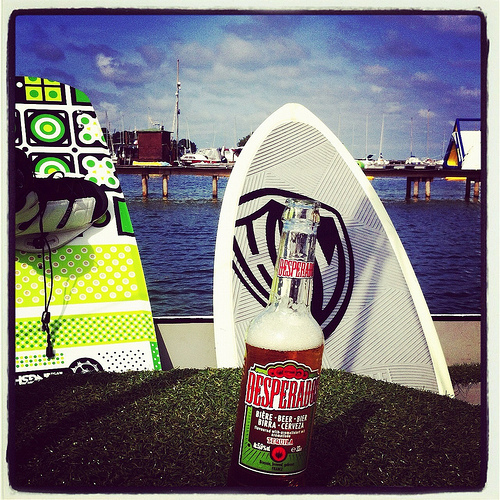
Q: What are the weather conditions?
A: It is cloudy.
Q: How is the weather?
A: It is cloudy.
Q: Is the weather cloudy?
A: Yes, it is cloudy.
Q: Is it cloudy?
A: Yes, it is cloudy.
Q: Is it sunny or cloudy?
A: It is cloudy.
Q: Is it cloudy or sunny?
A: It is cloudy.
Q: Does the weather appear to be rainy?
A: No, it is cloudy.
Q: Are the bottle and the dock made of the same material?
A: No, the bottle is made of glass and the dock is made of wood.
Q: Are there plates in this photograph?
A: No, there are no plates.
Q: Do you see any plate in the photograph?
A: No, there are no plates.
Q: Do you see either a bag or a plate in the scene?
A: No, there are no plates or bags.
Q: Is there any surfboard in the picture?
A: Yes, there is a surfboard.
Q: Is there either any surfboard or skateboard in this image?
A: Yes, there is a surfboard.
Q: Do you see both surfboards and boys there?
A: No, there is a surfboard but no boys.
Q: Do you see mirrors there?
A: No, there are no mirrors.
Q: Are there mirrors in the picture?
A: No, there are no mirrors.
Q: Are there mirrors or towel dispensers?
A: No, there are no mirrors or towel dispensers.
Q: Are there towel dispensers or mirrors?
A: No, there are no mirrors or towel dispensers.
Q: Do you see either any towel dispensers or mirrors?
A: No, there are no mirrors or towel dispensers.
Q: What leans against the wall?
A: The surf board leans against the wall.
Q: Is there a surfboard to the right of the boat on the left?
A: Yes, there is a surfboard to the right of the boat.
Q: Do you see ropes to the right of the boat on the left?
A: No, there is a surfboard to the right of the boat.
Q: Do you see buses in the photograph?
A: No, there are no buses.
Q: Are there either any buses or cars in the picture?
A: No, there are no buses or cars.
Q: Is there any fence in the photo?
A: No, there are no fences.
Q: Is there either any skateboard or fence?
A: No, there are no fences or skateboards.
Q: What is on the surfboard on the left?
A: The shoe is on the surfboard.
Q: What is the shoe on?
A: The shoe is on the surfboard.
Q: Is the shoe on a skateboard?
A: No, the shoe is on a surfboard.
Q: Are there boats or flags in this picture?
A: Yes, there is a boat.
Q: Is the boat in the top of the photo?
A: Yes, the boat is in the top of the image.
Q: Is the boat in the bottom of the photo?
A: No, the boat is in the top of the image.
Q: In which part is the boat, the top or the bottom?
A: The boat is in the top of the image.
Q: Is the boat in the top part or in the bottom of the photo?
A: The boat is in the top of the image.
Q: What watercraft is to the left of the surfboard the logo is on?
A: The watercraft is a boat.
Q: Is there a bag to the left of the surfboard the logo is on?
A: No, there is a boat to the left of the surfboard.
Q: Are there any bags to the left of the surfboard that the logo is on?
A: No, there is a boat to the left of the surfboard.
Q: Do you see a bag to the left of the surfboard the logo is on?
A: No, there is a boat to the left of the surfboard.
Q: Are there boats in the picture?
A: Yes, there is a boat.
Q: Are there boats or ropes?
A: Yes, there is a boat.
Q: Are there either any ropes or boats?
A: Yes, there is a boat.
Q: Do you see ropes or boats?
A: Yes, there is a boat.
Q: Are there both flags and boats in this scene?
A: No, there is a boat but no flags.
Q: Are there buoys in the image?
A: No, there are no buoys.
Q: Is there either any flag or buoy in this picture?
A: No, there are no buoys or flags.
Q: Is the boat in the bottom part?
A: No, the boat is in the top of the image.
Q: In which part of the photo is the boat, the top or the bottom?
A: The boat is in the top of the image.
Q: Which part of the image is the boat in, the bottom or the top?
A: The boat is in the top of the image.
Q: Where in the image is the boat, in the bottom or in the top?
A: The boat is in the top of the image.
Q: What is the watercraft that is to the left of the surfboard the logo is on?
A: The watercraft is a boat.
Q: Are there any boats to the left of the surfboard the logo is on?
A: Yes, there is a boat to the left of the surf board.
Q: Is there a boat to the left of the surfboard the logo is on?
A: Yes, there is a boat to the left of the surf board.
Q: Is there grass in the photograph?
A: Yes, there is grass.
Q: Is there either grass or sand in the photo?
A: Yes, there is grass.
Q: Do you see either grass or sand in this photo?
A: Yes, there is grass.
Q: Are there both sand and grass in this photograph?
A: No, there is grass but no sand.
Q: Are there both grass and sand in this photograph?
A: No, there is grass but no sand.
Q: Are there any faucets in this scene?
A: No, there are no faucets.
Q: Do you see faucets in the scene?
A: No, there are no faucets.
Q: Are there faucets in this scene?
A: No, there are no faucets.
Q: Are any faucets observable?
A: No, there are no faucets.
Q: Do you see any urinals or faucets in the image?
A: No, there are no faucets or urinals.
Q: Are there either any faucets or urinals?
A: No, there are no faucets or urinals.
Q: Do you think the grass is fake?
A: Yes, the grass is fake.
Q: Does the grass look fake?
A: Yes, the grass is fake.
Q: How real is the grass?
A: The grass is fake.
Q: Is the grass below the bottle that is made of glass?
A: Yes, the grass is below the bottle.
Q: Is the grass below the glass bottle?
A: Yes, the grass is below the bottle.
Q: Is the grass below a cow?
A: No, the grass is below the bottle.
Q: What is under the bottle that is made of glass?
A: The grass is under the bottle.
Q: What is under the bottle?
A: The grass is under the bottle.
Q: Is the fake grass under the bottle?
A: Yes, the grass is under the bottle.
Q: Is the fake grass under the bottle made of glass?
A: Yes, the grass is under the bottle.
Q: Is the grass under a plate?
A: No, the grass is under the bottle.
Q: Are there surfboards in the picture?
A: Yes, there is a surfboard.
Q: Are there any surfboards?
A: Yes, there is a surfboard.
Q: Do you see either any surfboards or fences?
A: Yes, there is a surfboard.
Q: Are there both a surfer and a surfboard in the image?
A: No, there is a surfboard but no surfers.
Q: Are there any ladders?
A: No, there are no ladders.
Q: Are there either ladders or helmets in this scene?
A: No, there are no ladders or helmets.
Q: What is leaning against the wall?
A: The surfboard is leaning against the wall.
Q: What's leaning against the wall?
A: The surfboard is leaning against the wall.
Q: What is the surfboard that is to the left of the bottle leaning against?
A: The surfboard is leaning against the wall.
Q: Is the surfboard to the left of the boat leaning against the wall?
A: Yes, the surfboard is leaning against the wall.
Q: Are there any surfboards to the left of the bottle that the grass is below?
A: Yes, there is a surfboard to the left of the bottle.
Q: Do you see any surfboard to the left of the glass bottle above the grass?
A: Yes, there is a surfboard to the left of the bottle.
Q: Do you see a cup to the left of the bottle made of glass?
A: No, there is a surfboard to the left of the bottle.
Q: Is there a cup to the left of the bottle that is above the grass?
A: No, there is a surfboard to the left of the bottle.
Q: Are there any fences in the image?
A: No, there are no fences.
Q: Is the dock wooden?
A: Yes, the dock is wooden.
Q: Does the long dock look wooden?
A: Yes, the pier is wooden.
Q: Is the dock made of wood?
A: Yes, the dock is made of wood.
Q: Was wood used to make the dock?
A: Yes, the dock is made of wood.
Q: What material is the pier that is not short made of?
A: The pier is made of wood.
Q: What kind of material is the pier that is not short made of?
A: The pier is made of wood.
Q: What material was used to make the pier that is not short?
A: The pier is made of wood.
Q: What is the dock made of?
A: The pier is made of wood.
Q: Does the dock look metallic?
A: No, the dock is wooden.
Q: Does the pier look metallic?
A: No, the pier is wooden.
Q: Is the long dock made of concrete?
A: No, the dock is made of wood.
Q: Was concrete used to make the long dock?
A: No, the dock is made of wood.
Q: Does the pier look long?
A: Yes, the pier is long.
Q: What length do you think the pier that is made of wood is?
A: The pier is long.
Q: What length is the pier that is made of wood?
A: The pier is long.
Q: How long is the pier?
A: The pier is long.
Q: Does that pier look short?
A: No, the pier is long.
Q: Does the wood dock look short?
A: No, the pier is long.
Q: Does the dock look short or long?
A: The dock is long.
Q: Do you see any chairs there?
A: No, there are no chairs.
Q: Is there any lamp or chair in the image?
A: No, there are no chairs or lamps.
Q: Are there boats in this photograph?
A: Yes, there is a boat.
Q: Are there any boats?
A: Yes, there is a boat.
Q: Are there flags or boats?
A: Yes, there is a boat.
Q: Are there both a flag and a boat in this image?
A: No, there is a boat but no flags.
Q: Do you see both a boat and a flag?
A: No, there is a boat but no flags.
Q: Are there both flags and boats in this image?
A: No, there is a boat but no flags.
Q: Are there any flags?
A: No, there are no flags.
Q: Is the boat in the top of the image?
A: Yes, the boat is in the top of the image.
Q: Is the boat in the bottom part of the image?
A: No, the boat is in the top of the image.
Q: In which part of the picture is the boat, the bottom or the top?
A: The boat is in the top of the image.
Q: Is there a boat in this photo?
A: Yes, there is a boat.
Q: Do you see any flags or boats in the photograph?
A: Yes, there is a boat.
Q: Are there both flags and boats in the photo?
A: No, there is a boat but no flags.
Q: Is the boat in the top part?
A: Yes, the boat is in the top of the image.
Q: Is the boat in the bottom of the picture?
A: No, the boat is in the top of the image.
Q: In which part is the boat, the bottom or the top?
A: The boat is in the top of the image.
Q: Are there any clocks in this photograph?
A: No, there are no clocks.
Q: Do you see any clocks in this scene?
A: No, there are no clocks.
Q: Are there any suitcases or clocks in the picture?
A: No, there are no clocks or suitcases.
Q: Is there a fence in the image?
A: No, there are no fences.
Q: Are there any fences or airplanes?
A: No, there are no fences or airplanes.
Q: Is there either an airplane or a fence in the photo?
A: No, there are no fences or airplanes.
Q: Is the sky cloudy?
A: Yes, the sky is cloudy.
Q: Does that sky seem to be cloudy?
A: Yes, the sky is cloudy.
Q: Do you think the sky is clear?
A: No, the sky is cloudy.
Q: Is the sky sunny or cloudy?
A: The sky is cloudy.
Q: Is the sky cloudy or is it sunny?
A: The sky is cloudy.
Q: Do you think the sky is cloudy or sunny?
A: The sky is cloudy.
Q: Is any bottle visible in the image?
A: Yes, there is a bottle.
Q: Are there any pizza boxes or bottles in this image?
A: Yes, there is a bottle.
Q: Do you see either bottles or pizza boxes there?
A: Yes, there is a bottle.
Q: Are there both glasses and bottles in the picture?
A: No, there is a bottle but no glasses.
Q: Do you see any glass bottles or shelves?
A: Yes, there is a glass bottle.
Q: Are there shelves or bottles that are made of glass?
A: Yes, the bottle is made of glass.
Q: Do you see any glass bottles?
A: Yes, there is a bottle that is made of glass.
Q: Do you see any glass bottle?
A: Yes, there is a bottle that is made of glass.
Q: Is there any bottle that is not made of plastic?
A: Yes, there is a bottle that is made of glass.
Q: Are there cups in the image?
A: No, there are no cups.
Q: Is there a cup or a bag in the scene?
A: No, there are no cups or bags.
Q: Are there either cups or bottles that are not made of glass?
A: No, there is a bottle but it is made of glass.